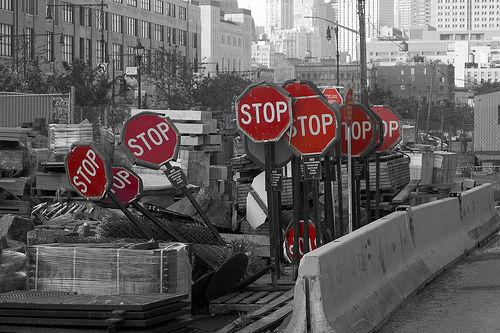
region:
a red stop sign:
[121, 109, 178, 169]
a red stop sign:
[63, 141, 110, 201]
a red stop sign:
[97, 162, 138, 209]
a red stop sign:
[236, 82, 291, 145]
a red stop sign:
[283, 94, 337, 156]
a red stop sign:
[334, 103, 375, 157]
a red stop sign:
[368, 101, 401, 156]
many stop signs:
[65, 75, 401, 266]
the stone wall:
[286, 176, 496, 327]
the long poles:
[326, 0, 371, 230]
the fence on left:
[0, 78, 76, 128]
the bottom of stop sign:
[196, 248, 251, 300]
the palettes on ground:
[207, 285, 292, 331]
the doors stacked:
[0, 287, 190, 328]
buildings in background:
[0, 0, 496, 100]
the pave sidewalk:
[380, 222, 496, 328]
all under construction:
[0, 74, 464, 331]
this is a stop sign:
[52, 143, 112, 193]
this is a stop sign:
[101, 156, 152, 217]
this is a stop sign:
[227, 75, 295, 152]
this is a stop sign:
[277, 88, 334, 168]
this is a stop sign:
[330, 96, 384, 170]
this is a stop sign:
[360, 86, 401, 160]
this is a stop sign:
[320, 68, 348, 108]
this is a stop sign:
[265, 199, 329, 281]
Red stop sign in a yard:
[72, 145, 117, 199]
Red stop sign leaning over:
[116, 106, 211, 193]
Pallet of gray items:
[31, 239, 202, 325]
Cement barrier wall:
[276, 212, 463, 332]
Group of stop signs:
[235, 73, 400, 175]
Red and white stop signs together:
[225, 70, 407, 179]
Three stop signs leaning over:
[61, 112, 228, 273]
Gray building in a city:
[375, 67, 461, 126]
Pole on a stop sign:
[161, 166, 241, 242]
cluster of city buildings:
[203, 2, 497, 104]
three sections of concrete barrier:
[286, 183, 495, 331]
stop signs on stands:
[66, 80, 401, 290]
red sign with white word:
[238, 86, 288, 139]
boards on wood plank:
[209, 291, 291, 314]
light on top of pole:
[131, 38, 145, 107]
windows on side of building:
[1, 0, 187, 106]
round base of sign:
[206, 251, 250, 300]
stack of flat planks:
[0, 288, 192, 330]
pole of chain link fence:
[0, 85, 75, 126]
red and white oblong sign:
[119, 108, 189, 169]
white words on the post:
[237, 99, 288, 121]